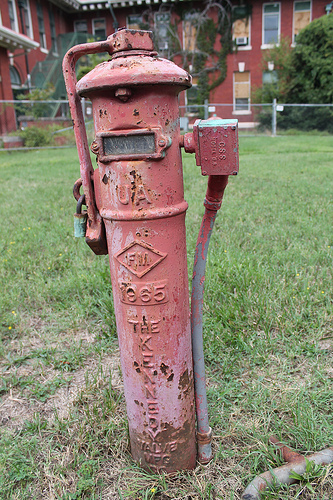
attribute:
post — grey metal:
[268, 97, 281, 135]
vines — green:
[188, 20, 229, 101]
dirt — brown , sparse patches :
[0, 321, 134, 489]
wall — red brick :
[280, 0, 292, 46]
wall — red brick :
[251, 0, 260, 120]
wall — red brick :
[207, 3, 232, 116]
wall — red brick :
[30, 0, 40, 40]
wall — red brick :
[107, 9, 126, 35]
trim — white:
[259, 1, 280, 49]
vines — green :
[182, 41, 236, 99]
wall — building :
[166, 32, 312, 130]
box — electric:
[196, 119, 239, 178]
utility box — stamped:
[59, 23, 242, 475]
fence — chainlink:
[55, 63, 326, 148]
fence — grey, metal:
[183, 102, 324, 145]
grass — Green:
[2, 137, 332, 499]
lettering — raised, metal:
[111, 182, 178, 471]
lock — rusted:
[56, 185, 94, 239]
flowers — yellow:
[7, 196, 65, 326]